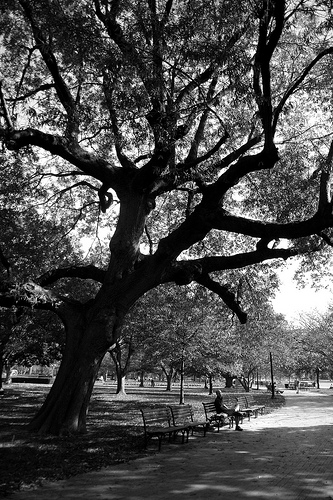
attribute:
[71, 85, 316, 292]
tree — large, group, many, shading, lining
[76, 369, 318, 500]
pathway — park, brick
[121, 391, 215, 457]
bench — park, row, wooden, empty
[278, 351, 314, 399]
person — walking, standing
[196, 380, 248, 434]
person — sitting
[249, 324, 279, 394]
light — street, black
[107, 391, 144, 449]
grass — lawn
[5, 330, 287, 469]
park — grassy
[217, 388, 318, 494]
sidewalk — brick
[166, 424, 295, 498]
walkway — paved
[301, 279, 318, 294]
sky — peeking